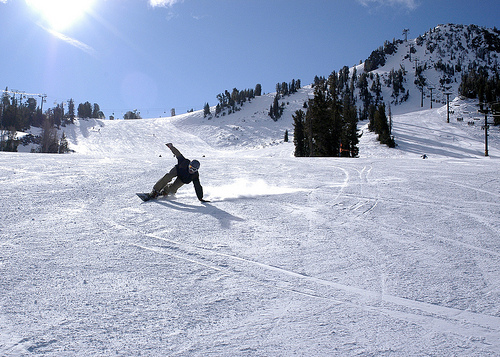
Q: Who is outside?
A: A man.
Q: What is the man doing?
A: The man is skiing.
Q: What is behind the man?
A: The mountains.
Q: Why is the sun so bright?
A: There are no clouds in front of it.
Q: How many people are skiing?
A: 1 person.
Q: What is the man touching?
A: The snow.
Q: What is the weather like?
A: Cold and sunny.